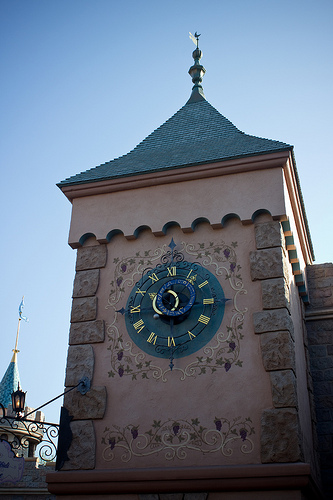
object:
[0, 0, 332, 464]
clear sky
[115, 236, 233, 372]
clock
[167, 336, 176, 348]
numeral 6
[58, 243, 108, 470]
brick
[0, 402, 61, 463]
metal scrooll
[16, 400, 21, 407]
lamp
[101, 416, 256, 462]
design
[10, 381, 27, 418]
lanter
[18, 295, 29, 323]
flag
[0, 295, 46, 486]
building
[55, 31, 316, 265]
roof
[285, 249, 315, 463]
side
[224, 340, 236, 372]
grapes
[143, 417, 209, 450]
vine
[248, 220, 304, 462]
brick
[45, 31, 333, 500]
building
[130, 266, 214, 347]
numeral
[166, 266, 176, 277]
twelve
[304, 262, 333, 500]
wall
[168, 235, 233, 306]
hands